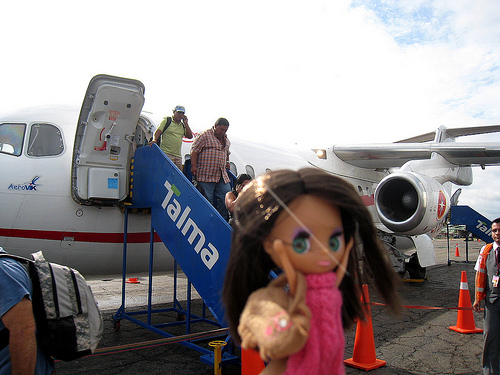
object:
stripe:
[458, 280, 472, 292]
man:
[192, 118, 232, 222]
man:
[154, 103, 194, 172]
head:
[173, 105, 189, 121]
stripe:
[358, 302, 377, 320]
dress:
[249, 273, 350, 373]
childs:
[224, 165, 406, 374]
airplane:
[0, 74, 499, 315]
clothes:
[238, 273, 343, 373]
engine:
[376, 172, 463, 235]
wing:
[337, 143, 500, 167]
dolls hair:
[222, 165, 398, 345]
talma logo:
[151, 181, 223, 270]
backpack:
[157, 117, 169, 138]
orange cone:
[448, 271, 482, 333]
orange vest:
[474, 247, 492, 310]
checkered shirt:
[193, 127, 229, 182]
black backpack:
[0, 251, 105, 362]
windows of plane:
[26, 123, 63, 156]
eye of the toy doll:
[290, 230, 308, 255]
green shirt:
[153, 112, 193, 162]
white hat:
[175, 105, 187, 112]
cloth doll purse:
[237, 271, 312, 359]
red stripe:
[0, 225, 163, 241]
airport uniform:
[469, 243, 500, 370]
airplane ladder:
[117, 142, 283, 363]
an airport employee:
[473, 215, 500, 366]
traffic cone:
[238, 350, 264, 375]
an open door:
[70, 74, 145, 207]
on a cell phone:
[181, 115, 189, 121]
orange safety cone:
[346, 284, 384, 370]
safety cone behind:
[454, 246, 461, 257]